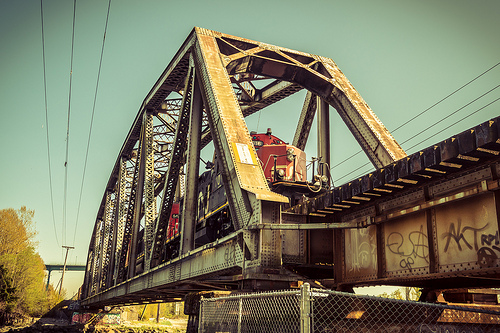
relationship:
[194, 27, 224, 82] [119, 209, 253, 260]
wall of bridge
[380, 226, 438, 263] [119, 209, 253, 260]
words on bridge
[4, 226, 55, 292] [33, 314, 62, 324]
trees near road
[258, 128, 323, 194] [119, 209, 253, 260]
train on bridge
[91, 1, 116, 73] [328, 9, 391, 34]
wire in sky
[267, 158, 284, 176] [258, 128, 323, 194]
light on train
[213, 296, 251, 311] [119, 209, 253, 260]
fence under bridge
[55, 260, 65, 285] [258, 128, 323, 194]
pole in front of train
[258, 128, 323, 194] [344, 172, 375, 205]
train on tracks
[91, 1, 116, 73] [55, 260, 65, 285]
wire on pole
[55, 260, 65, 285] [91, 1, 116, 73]
pole has wire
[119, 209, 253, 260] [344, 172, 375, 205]
bridge over tracks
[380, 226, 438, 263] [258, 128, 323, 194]
words on train